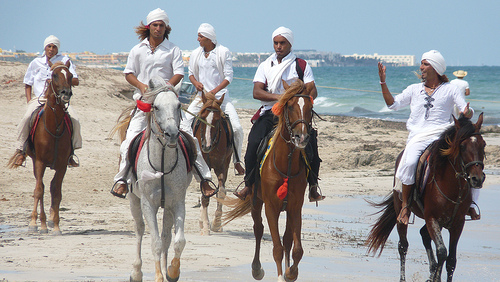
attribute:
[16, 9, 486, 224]
group — man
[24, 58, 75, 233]
horse — brown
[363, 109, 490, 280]
horse — brown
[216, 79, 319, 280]
horse — brown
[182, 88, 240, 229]
horse — brown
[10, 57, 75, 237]
horse — brown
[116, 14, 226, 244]
man — riding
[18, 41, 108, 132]
man — riding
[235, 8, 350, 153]
man — riding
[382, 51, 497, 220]
lady — riding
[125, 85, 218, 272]
horse — standing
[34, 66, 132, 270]
horse — standing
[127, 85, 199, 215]
horse — white